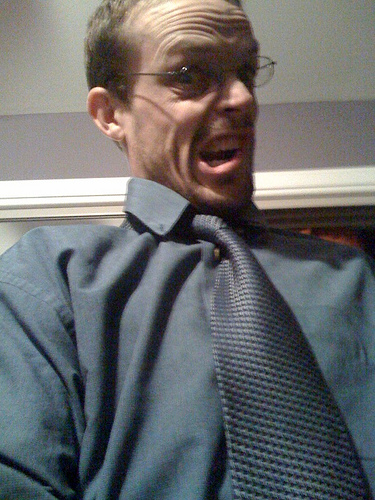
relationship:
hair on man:
[85, 0, 244, 153] [2, 2, 373, 499]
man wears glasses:
[2, 2, 373, 499] [97, 55, 279, 92]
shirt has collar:
[2, 175, 374, 496] [120, 175, 273, 239]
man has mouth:
[2, 2, 373, 499] [196, 121, 254, 177]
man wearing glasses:
[2, 2, 373, 499] [97, 55, 279, 92]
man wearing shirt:
[2, 2, 373, 499] [2, 175, 374, 496]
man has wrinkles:
[2, 2, 373, 499] [145, 4, 255, 64]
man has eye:
[2, 2, 373, 499] [174, 62, 205, 84]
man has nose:
[2, 2, 373, 499] [213, 67, 250, 115]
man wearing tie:
[2, 2, 373, 499] [189, 211, 374, 499]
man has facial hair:
[2, 2, 373, 499] [192, 111, 255, 146]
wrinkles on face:
[145, 4, 255, 64] [128, 2, 258, 208]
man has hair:
[2, 2, 373, 499] [85, 0, 244, 153]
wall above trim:
[0, 96, 375, 183] [0, 162, 375, 225]